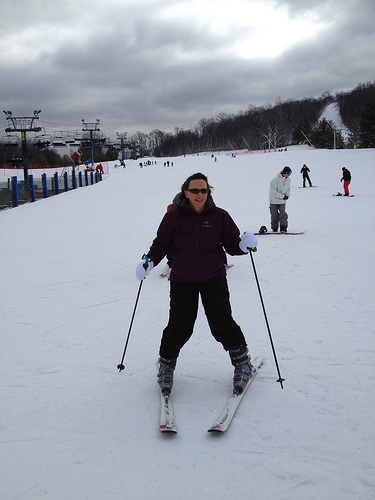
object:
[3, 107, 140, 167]
chair lift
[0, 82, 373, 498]
ski resort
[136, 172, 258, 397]
skier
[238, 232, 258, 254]
glove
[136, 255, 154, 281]
glove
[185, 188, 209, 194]
sunglasses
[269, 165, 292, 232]
skier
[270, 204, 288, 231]
pants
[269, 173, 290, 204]
jacket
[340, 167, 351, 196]
skier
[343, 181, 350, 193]
pants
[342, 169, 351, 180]
jacket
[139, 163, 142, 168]
skiers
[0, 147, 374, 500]
slope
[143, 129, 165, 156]
trees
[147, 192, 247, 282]
jacket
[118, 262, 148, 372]
ski pole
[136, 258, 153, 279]
hand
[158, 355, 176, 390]
ski boot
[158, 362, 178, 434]
ski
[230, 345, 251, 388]
ski boot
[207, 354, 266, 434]
ski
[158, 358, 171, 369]
binder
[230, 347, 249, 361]
binder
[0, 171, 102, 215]
fence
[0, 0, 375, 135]
sky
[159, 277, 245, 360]
pants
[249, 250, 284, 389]
ski pole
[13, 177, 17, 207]
post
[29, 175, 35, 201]
post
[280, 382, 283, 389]
point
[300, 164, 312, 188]
person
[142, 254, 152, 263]
strap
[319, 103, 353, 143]
snow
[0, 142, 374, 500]
snow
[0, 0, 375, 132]
clouds